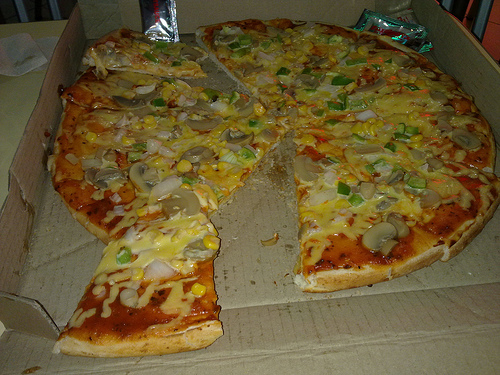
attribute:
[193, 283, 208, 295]
corn — single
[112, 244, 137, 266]
bell pepper — chopped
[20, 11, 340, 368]
box — cardboard